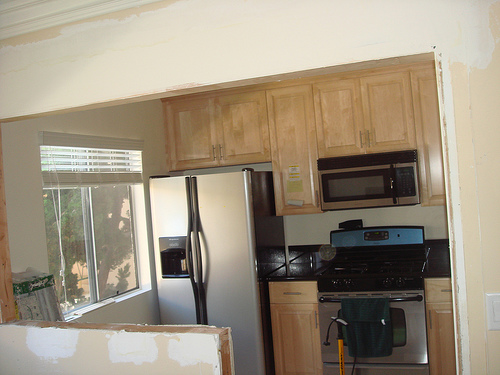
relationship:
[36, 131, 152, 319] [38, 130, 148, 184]
window with blinds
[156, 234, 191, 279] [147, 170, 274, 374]
ice maker on fridge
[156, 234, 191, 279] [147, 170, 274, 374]
ice maker built into fridge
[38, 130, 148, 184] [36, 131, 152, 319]
blinds hanging above window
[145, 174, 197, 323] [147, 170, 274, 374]
door leading to fridge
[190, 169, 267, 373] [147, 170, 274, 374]
door leading to fridge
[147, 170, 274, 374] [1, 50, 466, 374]
fridge standing inside kitchen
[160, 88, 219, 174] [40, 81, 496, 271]
cabinet hanging inside kitchen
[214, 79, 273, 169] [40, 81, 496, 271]
cabinet hanging inside kitchen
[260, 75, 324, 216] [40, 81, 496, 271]
cabinet hanging inside kitchen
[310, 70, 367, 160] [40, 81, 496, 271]
cabinet hanging inside kitchen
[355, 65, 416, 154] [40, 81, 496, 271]
cabinet hanging inside kitchen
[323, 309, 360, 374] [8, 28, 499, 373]
pump standing inside kitchen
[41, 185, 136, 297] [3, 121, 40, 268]
window adorning wall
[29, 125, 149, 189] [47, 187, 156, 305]
blinds hanging above window